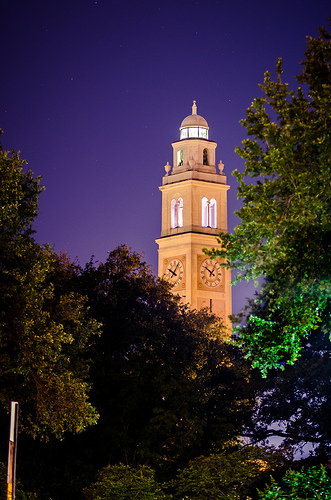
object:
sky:
[0, 0, 331, 466]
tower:
[154, 100, 232, 349]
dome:
[179, 114, 209, 130]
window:
[200, 195, 209, 227]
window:
[170, 198, 177, 230]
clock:
[199, 256, 222, 290]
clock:
[165, 258, 185, 289]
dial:
[205, 263, 217, 282]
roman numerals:
[210, 259, 213, 264]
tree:
[200, 23, 331, 381]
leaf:
[243, 140, 253, 150]